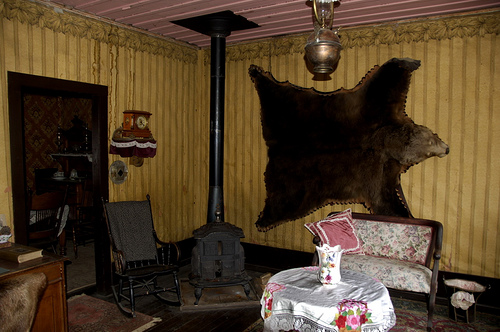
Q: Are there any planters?
A: No, there are no planters.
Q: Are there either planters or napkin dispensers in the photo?
A: No, there are no planters or napkin dispensers.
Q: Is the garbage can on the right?
A: Yes, the garbage can is on the right of the image.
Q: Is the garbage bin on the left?
A: No, the garbage bin is on the right of the image.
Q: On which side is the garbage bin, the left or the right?
A: The garbage bin is on the right of the image.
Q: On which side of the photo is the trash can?
A: The trash can is on the right of the image.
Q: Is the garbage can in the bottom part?
A: Yes, the garbage can is in the bottom of the image.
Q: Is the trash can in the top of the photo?
A: No, the trash can is in the bottom of the image.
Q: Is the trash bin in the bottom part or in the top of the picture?
A: The trash bin is in the bottom of the image.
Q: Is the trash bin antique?
A: Yes, the trash bin is antique.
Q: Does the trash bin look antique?
A: Yes, the trash bin is antique.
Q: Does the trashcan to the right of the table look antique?
A: Yes, the trash bin is antique.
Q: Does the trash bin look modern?
A: No, the trash bin is antique.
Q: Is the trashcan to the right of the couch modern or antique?
A: The trash bin is antique.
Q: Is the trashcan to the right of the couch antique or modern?
A: The trash bin is antique.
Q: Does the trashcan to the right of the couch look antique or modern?
A: The trash bin is antique.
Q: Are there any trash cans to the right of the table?
A: Yes, there is a trash can to the right of the table.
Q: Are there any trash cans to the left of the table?
A: No, the trash can is to the right of the table.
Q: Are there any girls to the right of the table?
A: No, there is a trash can to the right of the table.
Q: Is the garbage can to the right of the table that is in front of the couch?
A: Yes, the garbage can is to the right of the table.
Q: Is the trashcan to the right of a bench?
A: No, the trashcan is to the right of the table.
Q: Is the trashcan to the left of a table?
A: No, the trashcan is to the right of a table.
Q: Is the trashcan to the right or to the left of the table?
A: The trashcan is to the right of the table.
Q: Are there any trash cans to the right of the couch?
A: Yes, there is a trash can to the right of the couch.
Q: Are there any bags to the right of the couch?
A: No, there is a trash can to the right of the couch.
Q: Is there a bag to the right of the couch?
A: No, there is a trash can to the right of the couch.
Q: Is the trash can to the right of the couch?
A: Yes, the trash can is to the right of the couch.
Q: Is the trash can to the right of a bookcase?
A: No, the trash can is to the right of the couch.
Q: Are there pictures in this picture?
A: No, there are no pictures.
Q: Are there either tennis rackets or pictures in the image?
A: No, there are no pictures or tennis rackets.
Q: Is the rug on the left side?
A: Yes, the rug is on the left of the image.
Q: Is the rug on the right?
A: No, the rug is on the left of the image.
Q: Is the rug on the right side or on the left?
A: The rug is on the left of the image.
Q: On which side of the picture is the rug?
A: The rug is on the left of the image.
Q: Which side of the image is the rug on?
A: The rug is on the left of the image.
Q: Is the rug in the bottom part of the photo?
A: Yes, the rug is in the bottom of the image.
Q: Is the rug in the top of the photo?
A: No, the rug is in the bottom of the image.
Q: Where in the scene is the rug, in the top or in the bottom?
A: The rug is in the bottom of the image.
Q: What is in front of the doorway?
A: The rug is in front of the doorway.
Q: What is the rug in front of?
A: The rug is in front of the doorway.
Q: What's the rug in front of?
A: The rug is in front of the doorway.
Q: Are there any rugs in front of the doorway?
A: Yes, there is a rug in front of the doorway.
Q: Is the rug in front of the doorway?
A: Yes, the rug is in front of the doorway.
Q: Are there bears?
A: Yes, there is a bear.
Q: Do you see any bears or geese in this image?
A: Yes, there is a bear.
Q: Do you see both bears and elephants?
A: No, there is a bear but no elephants.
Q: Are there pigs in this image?
A: No, there are no pigs.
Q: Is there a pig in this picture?
A: No, there are no pigs.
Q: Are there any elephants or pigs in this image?
A: No, there are no pigs or elephants.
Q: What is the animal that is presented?
A: The animal is a bear.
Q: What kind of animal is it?
A: The animal is a bear.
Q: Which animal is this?
A: This is a bear.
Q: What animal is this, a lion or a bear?
A: This is a bear.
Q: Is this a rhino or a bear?
A: This is a bear.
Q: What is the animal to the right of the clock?
A: The animal is a bear.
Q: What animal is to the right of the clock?
A: The animal is a bear.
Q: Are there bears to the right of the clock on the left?
A: Yes, there is a bear to the right of the clock.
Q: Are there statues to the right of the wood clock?
A: No, there is a bear to the right of the clock.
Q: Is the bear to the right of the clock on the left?
A: Yes, the bear is to the right of the clock.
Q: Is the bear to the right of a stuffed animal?
A: No, the bear is to the right of the clock.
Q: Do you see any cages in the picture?
A: No, there are no cages.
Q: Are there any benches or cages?
A: No, there are no cages or benches.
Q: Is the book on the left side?
A: Yes, the book is on the left of the image.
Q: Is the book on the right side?
A: No, the book is on the left of the image.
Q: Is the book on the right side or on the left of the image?
A: The book is on the left of the image.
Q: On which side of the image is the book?
A: The book is on the left of the image.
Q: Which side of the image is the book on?
A: The book is on the left of the image.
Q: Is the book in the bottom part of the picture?
A: Yes, the book is in the bottom of the image.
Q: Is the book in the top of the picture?
A: No, the book is in the bottom of the image.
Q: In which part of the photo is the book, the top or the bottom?
A: The book is in the bottom of the image.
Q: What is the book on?
A: The book is on the counter.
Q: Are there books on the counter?
A: Yes, there is a book on the counter.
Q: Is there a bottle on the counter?
A: No, there is a book on the counter.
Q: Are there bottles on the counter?
A: No, there is a book on the counter.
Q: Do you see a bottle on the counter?
A: No, there is a book on the counter.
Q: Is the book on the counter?
A: Yes, the book is on the counter.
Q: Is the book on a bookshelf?
A: No, the book is on the counter.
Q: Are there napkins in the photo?
A: No, there are no napkins.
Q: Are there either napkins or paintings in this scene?
A: No, there are no napkins or paintings.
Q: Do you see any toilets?
A: No, there are no toilets.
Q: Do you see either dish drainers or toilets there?
A: No, there are no toilets or dish drainers.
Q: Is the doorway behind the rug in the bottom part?
A: Yes, the doorway is behind the rug.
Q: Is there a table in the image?
A: Yes, there is a table.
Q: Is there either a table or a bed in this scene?
A: Yes, there is a table.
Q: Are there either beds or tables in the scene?
A: Yes, there is a table.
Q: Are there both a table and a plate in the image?
A: No, there is a table but no plates.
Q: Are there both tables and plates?
A: No, there is a table but no plates.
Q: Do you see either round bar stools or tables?
A: Yes, there is a round table.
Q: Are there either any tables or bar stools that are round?
A: Yes, the table is round.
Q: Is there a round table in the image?
A: Yes, there is a round table.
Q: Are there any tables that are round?
A: Yes, there is a table that is round.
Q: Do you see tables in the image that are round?
A: Yes, there is a table that is round.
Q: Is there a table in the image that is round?
A: Yes, there is a table that is round.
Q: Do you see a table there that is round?
A: Yes, there is a table that is round.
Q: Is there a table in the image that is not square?
A: Yes, there is a round table.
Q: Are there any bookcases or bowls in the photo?
A: No, there are no bookcases or bowls.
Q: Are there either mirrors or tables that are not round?
A: No, there is a table but it is round.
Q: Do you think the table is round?
A: Yes, the table is round.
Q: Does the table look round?
A: Yes, the table is round.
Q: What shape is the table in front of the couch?
A: The table is round.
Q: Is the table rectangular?
A: No, the table is round.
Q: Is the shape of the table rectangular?
A: No, the table is round.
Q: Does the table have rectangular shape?
A: No, the table is round.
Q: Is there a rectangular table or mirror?
A: No, there is a table but it is round.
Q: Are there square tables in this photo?
A: No, there is a table but it is round.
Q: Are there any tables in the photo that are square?
A: No, there is a table but it is round.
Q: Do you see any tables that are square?
A: No, there is a table but it is round.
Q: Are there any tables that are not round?
A: No, there is a table but it is round.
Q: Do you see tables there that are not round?
A: No, there is a table but it is round.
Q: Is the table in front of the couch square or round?
A: The table is round.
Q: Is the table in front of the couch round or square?
A: The table is round.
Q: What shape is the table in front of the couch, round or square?
A: The table is round.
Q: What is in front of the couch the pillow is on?
A: The table is in front of the couch.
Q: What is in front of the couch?
A: The table is in front of the couch.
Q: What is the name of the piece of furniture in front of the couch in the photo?
A: The piece of furniture is a table.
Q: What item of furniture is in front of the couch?
A: The piece of furniture is a table.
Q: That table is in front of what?
A: The table is in front of the couch.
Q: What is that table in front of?
A: The table is in front of the couch.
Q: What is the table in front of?
A: The table is in front of the couch.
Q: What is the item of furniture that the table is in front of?
A: The piece of furniture is a couch.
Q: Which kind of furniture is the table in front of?
A: The table is in front of the couch.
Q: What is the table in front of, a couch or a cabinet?
A: The table is in front of a couch.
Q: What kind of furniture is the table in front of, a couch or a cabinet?
A: The table is in front of a couch.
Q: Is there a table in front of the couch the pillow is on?
A: Yes, there is a table in front of the couch.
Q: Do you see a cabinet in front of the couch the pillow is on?
A: No, there is a table in front of the couch.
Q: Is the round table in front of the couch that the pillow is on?
A: Yes, the table is in front of the couch.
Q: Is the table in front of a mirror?
A: No, the table is in front of the couch.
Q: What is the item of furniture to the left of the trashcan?
A: The piece of furniture is a table.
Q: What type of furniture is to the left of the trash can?
A: The piece of furniture is a table.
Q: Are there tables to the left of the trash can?
A: Yes, there is a table to the left of the trash can.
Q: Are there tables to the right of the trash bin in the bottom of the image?
A: No, the table is to the left of the garbage bin.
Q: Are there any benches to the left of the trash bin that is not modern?
A: No, there is a table to the left of the garbage bin.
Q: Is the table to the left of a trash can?
A: Yes, the table is to the left of a trash can.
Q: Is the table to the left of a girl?
A: No, the table is to the left of a trash can.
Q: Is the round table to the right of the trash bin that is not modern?
A: No, the table is to the left of the garbage bin.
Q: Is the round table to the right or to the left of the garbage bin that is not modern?
A: The table is to the left of the garbage bin.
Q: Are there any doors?
A: Yes, there is a door.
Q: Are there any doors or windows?
A: Yes, there is a door.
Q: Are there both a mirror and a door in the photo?
A: No, there is a door but no mirrors.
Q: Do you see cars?
A: No, there are no cars.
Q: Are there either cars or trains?
A: No, there are no cars or trains.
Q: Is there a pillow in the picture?
A: Yes, there is a pillow.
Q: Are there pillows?
A: Yes, there is a pillow.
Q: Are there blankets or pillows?
A: Yes, there is a pillow.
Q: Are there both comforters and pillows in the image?
A: No, there is a pillow but no comforters.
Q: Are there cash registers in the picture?
A: No, there are no cash registers.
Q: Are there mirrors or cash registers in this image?
A: No, there are no cash registers or mirrors.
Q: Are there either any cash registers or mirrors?
A: No, there are no cash registers or mirrors.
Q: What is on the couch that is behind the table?
A: The pillow is on the couch.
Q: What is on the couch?
A: The pillow is on the couch.